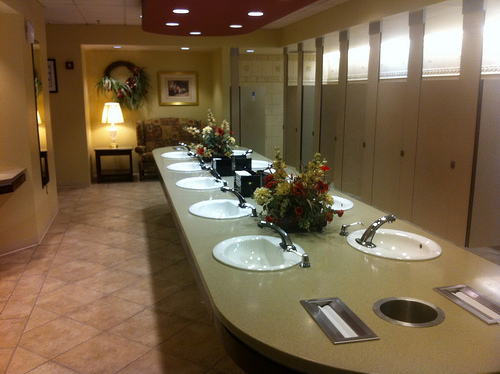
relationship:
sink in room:
[212, 219, 313, 279] [9, 8, 499, 270]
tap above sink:
[258, 217, 299, 250] [212, 219, 313, 279]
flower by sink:
[258, 148, 338, 221] [212, 219, 313, 279]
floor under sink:
[60, 196, 162, 311] [212, 219, 313, 279]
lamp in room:
[89, 95, 131, 153] [9, 8, 499, 270]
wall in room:
[10, 72, 37, 173] [9, 8, 499, 270]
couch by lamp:
[133, 113, 192, 145] [89, 95, 131, 153]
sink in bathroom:
[212, 219, 313, 279] [9, 8, 499, 270]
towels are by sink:
[230, 169, 253, 192] [212, 219, 313, 279]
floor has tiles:
[60, 196, 162, 311] [93, 250, 126, 267]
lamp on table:
[89, 95, 131, 153] [91, 145, 138, 179]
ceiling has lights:
[50, 4, 334, 40] [175, 4, 201, 18]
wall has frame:
[10, 72, 37, 173] [156, 67, 201, 111]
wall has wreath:
[10, 72, 37, 173] [100, 61, 146, 104]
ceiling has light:
[50, 4, 334, 40] [244, 6, 265, 22]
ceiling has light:
[50, 4, 334, 40] [186, 27, 205, 39]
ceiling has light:
[50, 4, 334, 40] [220, 20, 242, 33]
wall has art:
[10, 72, 37, 173] [156, 67, 201, 111]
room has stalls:
[9, 8, 499, 270] [352, 84, 468, 213]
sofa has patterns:
[133, 113, 192, 145] [157, 124, 183, 139]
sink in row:
[212, 219, 313, 279] [164, 151, 306, 283]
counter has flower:
[304, 232, 349, 271] [258, 148, 338, 221]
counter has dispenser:
[304, 232, 349, 271] [298, 290, 384, 351]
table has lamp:
[91, 145, 138, 179] [89, 95, 131, 153]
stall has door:
[266, 88, 283, 143] [244, 89, 275, 140]